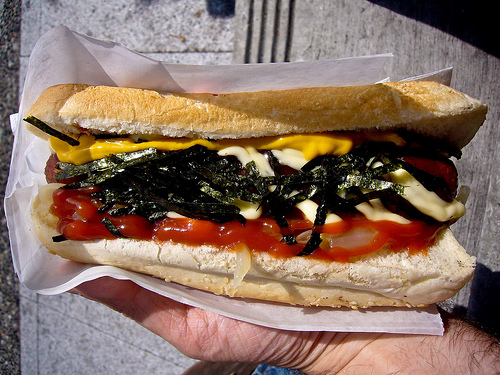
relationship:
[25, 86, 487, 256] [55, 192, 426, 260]
sandwich has ketchup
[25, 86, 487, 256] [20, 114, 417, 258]
sandwich has seaweed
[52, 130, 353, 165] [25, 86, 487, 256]
mustard on sandwich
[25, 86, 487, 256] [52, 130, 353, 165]
sandwich has mustard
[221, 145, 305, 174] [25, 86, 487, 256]
bead on sandwich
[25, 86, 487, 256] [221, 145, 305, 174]
sandwich has bead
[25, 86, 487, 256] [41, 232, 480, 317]
sandwich has bottom bread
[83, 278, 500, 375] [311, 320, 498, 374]
human has arm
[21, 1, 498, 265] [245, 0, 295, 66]
brick has lines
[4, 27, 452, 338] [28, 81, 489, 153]
wrapper under bun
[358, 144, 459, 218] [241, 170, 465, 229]
hot dog has topping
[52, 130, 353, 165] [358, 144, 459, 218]
mustard on hot dog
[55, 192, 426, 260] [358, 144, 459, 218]
ketchup on hot dog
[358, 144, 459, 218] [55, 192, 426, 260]
hot dog has ketchup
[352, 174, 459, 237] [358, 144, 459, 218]
mayo on hot dog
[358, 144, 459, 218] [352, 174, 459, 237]
hot dog has mayo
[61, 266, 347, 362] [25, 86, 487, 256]
hand under hotdog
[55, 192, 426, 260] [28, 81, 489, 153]
ketchup near bun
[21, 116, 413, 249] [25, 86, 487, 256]
seaweed on sandwich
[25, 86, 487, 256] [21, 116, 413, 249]
sandwich has seaweed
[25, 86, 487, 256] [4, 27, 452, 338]
sandwich in wrapper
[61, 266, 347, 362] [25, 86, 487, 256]
hand holding sandwich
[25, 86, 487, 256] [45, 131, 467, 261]
sandwich has filling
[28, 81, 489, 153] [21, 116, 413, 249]
bun has seaweed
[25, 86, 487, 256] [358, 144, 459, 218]
sandwich has hot dog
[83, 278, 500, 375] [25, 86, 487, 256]
human holding sandwich